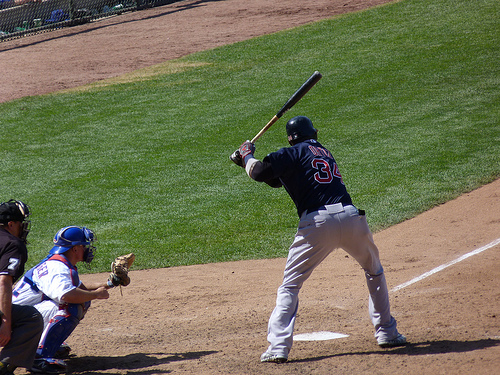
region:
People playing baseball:
[10, 67, 415, 373]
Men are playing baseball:
[9, 67, 406, 371]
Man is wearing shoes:
[257, 325, 411, 365]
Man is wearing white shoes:
[255, 334, 411, 361]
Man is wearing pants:
[262, 200, 407, 356]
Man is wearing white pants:
[263, 203, 403, 355]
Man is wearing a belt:
[295, 197, 360, 215]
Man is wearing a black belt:
[292, 199, 359, 219]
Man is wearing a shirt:
[256, 137, 356, 212]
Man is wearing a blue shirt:
[254, 140, 364, 212]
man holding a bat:
[231, 69, 413, 361]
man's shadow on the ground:
[286, 336, 498, 372]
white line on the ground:
[387, 219, 498, 299]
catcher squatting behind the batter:
[13, 224, 136, 371]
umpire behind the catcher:
[1, 198, 45, 374]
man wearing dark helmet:
[238, 115, 413, 369]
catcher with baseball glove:
[12, 226, 136, 374]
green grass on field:
[0, 0, 499, 278]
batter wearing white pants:
[260, 201, 409, 365]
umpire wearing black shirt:
[1, 196, 44, 374]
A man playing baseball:
[224, 63, 420, 367]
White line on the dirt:
[387, 236, 498, 294]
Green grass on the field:
[1, 1, 498, 272]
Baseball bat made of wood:
[228, 67, 324, 170]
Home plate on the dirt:
[281, 323, 352, 351]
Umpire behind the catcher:
[1, 192, 138, 373]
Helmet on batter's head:
[281, 111, 323, 151]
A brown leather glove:
[110, 246, 137, 291]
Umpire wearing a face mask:
[1, 194, 35, 250]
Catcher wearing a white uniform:
[11, 224, 93, 369]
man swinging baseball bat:
[247, 20, 424, 360]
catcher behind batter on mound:
[38, 198, 143, 373]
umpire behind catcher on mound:
[11, 197, 52, 374]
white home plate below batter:
[280, 312, 364, 364]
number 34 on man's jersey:
[309, 144, 369, 201]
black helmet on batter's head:
[252, 110, 312, 132]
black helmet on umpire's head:
[4, 197, 46, 230]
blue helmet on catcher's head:
[58, 215, 125, 259]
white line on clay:
[415, 205, 492, 267]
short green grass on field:
[45, 57, 466, 249]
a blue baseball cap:
[46, 225, 83, 254]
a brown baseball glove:
[109, 252, 140, 292]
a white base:
[284, 323, 346, 344]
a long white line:
[380, 234, 498, 300]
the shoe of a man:
[254, 345, 287, 362]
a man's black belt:
[301, 199, 353, 211]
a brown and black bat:
[247, 66, 324, 143]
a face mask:
[82, 226, 99, 263]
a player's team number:
[307, 157, 348, 185]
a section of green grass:
[0, 0, 499, 272]